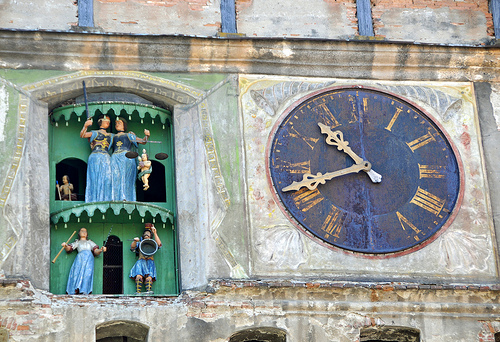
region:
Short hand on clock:
[308, 120, 370, 160]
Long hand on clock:
[278, 162, 363, 197]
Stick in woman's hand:
[48, 227, 78, 269]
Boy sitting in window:
[49, 170, 82, 203]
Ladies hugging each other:
[78, 114, 153, 150]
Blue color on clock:
[386, 140, 406, 181]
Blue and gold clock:
[251, 77, 476, 262]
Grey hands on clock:
[266, 110, 391, 208]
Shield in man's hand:
[129, 233, 161, 260]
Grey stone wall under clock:
[218, 287, 357, 318]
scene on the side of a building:
[43, 79, 195, 310]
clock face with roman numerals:
[256, 77, 491, 270]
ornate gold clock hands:
[276, 119, 383, 209]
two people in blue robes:
[76, 110, 168, 214]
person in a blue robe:
[51, 220, 113, 297]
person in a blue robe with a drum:
[122, 221, 167, 293]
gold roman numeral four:
[405, 180, 450, 217]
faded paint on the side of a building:
[399, 76, 493, 122]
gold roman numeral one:
[381, 94, 406, 136]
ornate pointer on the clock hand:
[316, 119, 356, 159]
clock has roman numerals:
[260, 75, 494, 270]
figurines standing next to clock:
[10, 55, 227, 312]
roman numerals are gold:
[232, 97, 474, 254]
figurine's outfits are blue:
[0, 80, 210, 335]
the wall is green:
[44, 80, 205, 308]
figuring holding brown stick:
[42, 223, 89, 271]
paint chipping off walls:
[1, 0, 496, 340]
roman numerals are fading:
[259, 91, 472, 271]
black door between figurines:
[101, 230, 131, 298]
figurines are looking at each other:
[58, 96, 161, 201]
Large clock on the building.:
[266, 85, 471, 258]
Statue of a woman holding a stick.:
[51, 226, 110, 292]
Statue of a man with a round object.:
[128, 223, 161, 293]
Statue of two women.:
[78, 78, 153, 203]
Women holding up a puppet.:
[73, 78, 160, 210]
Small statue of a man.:
[56, 172, 76, 201]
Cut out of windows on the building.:
[87, 313, 426, 340]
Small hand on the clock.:
[317, 121, 382, 190]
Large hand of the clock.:
[280, 149, 375, 201]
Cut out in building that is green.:
[47, 89, 187, 299]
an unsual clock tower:
[6, 18, 471, 327]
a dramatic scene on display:
[26, 61, 203, 327]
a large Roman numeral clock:
[241, 59, 488, 304]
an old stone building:
[1, 4, 498, 114]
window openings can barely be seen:
[40, 291, 491, 339]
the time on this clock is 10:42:
[261, 89, 383, 232]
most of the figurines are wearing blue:
[55, 114, 191, 301]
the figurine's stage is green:
[54, 105, 173, 296]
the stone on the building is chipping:
[198, 249, 498, 314]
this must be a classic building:
[18, 24, 464, 339]